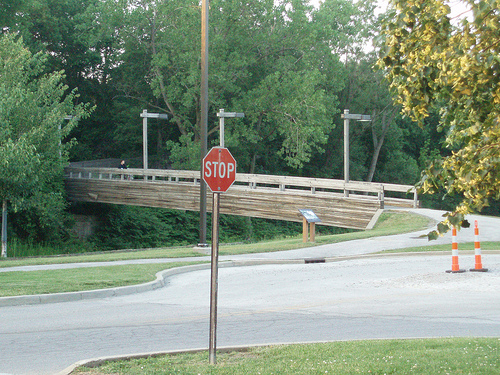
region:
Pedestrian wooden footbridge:
[62, 131, 454, 228]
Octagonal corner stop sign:
[199, 139, 243, 368]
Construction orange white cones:
[442, 208, 497, 286]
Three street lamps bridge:
[136, 89, 384, 146]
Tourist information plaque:
[282, 206, 340, 245]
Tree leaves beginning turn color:
[379, 3, 494, 203]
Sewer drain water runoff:
[293, 254, 349, 273]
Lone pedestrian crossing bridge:
[106, 141, 141, 190]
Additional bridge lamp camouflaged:
[47, 104, 80, 195]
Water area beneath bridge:
[93, 205, 306, 244]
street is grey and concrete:
[210, 270, 440, 327]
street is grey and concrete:
[259, 272, 382, 317]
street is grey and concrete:
[248, 288, 428, 343]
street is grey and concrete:
[276, 293, 433, 314]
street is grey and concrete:
[258, 277, 465, 360]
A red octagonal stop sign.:
[200, 144, 238, 191]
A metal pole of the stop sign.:
[210, 189, 218, 365]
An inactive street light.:
[341, 106, 369, 182]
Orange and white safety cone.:
[448, 222, 462, 277]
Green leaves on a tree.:
[399, 51, 421, 76]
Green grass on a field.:
[263, 351, 295, 366]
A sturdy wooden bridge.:
[63, 159, 420, 233]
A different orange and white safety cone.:
[470, 219, 487, 273]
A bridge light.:
[140, 106, 168, 168]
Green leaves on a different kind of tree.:
[31, 77, 53, 98]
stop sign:
[194, 141, 242, 372]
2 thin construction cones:
[443, 215, 490, 278]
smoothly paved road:
[1, 249, 498, 372]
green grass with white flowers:
[73, 333, 498, 371]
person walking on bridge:
[113, 158, 132, 182]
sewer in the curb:
[301, 253, 332, 270]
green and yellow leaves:
[366, 2, 499, 245]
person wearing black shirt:
[113, 153, 133, 185]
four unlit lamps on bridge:
[49, 100, 384, 200]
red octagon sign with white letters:
[196, 142, 242, 201]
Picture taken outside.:
[33, 12, 478, 373]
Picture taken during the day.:
[33, 23, 465, 355]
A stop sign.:
[187, 160, 293, 243]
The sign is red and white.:
[174, 111, 297, 246]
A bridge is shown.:
[77, 100, 456, 327]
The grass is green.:
[311, 349, 474, 366]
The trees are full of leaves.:
[13, 8, 347, 166]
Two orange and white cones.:
[439, 186, 484, 293]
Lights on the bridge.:
[127, 68, 435, 204]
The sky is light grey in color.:
[315, 10, 433, 66]